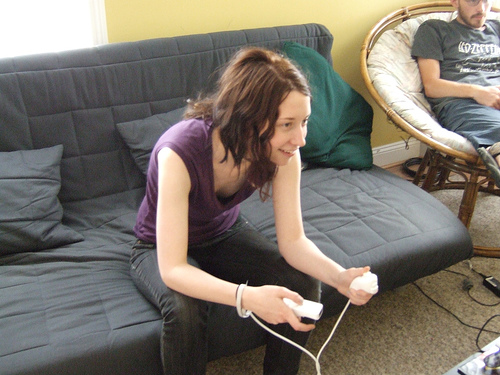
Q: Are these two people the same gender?
A: No, they are both male and female.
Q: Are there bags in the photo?
A: No, there are no bags.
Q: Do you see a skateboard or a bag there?
A: No, there are no bags or skateboards.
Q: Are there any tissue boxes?
A: No, there are no tissue boxes.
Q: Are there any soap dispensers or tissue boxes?
A: No, there are no tissue boxes or soap dispensers.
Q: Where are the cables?
A: The cables are on the floor.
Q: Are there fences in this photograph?
A: No, there are no fences.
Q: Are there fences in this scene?
A: No, there are no fences.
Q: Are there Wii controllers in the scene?
A: Yes, there is a Wii controller.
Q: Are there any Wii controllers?
A: Yes, there is a Wii controller.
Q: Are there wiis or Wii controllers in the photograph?
A: Yes, there is a Wii controller.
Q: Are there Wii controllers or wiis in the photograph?
A: Yes, there is a Wii controller.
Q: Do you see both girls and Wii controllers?
A: Yes, there are both a Wii controller and a girl.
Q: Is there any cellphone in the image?
A: No, there are no cell phones.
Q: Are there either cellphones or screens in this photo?
A: No, there are no cellphones or screens.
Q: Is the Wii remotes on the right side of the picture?
A: Yes, the Wii remotes is on the right of the image.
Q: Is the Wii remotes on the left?
A: No, the Wii remotes is on the right of the image.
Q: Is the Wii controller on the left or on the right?
A: The Wii controller is on the right of the image.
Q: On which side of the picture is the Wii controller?
A: The Wii controller is on the right of the image.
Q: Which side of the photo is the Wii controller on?
A: The Wii controller is on the right of the image.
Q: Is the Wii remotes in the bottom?
A: Yes, the Wii remotes is in the bottom of the image.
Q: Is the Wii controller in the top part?
A: No, the Wii controller is in the bottom of the image.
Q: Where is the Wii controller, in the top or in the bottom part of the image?
A: The Wii controller is in the bottom of the image.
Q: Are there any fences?
A: No, there are no fences.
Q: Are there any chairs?
A: Yes, there is a chair.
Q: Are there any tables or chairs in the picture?
A: Yes, there is a chair.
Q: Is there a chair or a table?
A: Yes, there is a chair.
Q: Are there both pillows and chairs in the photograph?
A: Yes, there are both a chair and a pillow.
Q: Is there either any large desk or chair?
A: Yes, there is a large chair.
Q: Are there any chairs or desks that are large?
A: Yes, the chair is large.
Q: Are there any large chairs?
A: Yes, there is a large chair.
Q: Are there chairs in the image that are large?
A: Yes, there is a chair that is large.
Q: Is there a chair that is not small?
A: Yes, there is a large chair.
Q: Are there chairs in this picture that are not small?
A: Yes, there is a large chair.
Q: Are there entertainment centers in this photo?
A: No, there are no entertainment centers.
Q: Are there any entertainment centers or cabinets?
A: No, there are no entertainment centers or cabinets.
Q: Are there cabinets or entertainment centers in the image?
A: No, there are no entertainment centers or cabinets.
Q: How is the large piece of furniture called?
A: The piece of furniture is a chair.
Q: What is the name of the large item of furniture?
A: The piece of furniture is a chair.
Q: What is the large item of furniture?
A: The piece of furniture is a chair.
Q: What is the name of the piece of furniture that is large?
A: The piece of furniture is a chair.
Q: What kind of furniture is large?
A: The furniture is a chair.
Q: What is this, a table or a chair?
A: This is a chair.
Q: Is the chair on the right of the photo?
A: Yes, the chair is on the right of the image.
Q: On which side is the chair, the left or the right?
A: The chair is on the right of the image.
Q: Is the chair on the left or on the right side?
A: The chair is on the right of the image.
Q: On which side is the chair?
A: The chair is on the right of the image.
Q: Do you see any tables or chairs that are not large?
A: No, there is a chair but it is large.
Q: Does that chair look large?
A: Yes, the chair is large.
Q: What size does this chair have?
A: The chair has large size.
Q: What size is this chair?
A: The chair is large.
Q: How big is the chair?
A: The chair is large.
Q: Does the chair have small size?
A: No, the chair is large.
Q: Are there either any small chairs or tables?
A: No, there is a chair but it is large.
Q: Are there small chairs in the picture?
A: No, there is a chair but it is large.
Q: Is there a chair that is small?
A: No, there is a chair but it is large.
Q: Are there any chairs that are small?
A: No, there is a chair but it is large.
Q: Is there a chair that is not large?
A: No, there is a chair but it is large.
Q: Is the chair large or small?
A: The chair is large.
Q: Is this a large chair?
A: Yes, this is a large chair.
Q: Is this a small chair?
A: No, this is a large chair.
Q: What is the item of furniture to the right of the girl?
A: The piece of furniture is a chair.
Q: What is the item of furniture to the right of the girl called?
A: The piece of furniture is a chair.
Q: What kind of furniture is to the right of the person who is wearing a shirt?
A: The piece of furniture is a chair.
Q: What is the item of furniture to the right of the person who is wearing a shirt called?
A: The piece of furniture is a chair.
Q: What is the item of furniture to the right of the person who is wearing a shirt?
A: The piece of furniture is a chair.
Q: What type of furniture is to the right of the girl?
A: The piece of furniture is a chair.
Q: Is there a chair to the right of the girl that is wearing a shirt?
A: Yes, there is a chair to the right of the girl.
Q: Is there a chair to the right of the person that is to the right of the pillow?
A: Yes, there is a chair to the right of the girl.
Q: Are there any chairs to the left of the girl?
A: No, the chair is to the right of the girl.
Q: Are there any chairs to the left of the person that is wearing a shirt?
A: No, the chair is to the right of the girl.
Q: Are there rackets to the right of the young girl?
A: No, there is a chair to the right of the girl.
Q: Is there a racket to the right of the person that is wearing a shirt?
A: No, there is a chair to the right of the girl.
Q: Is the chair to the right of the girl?
A: Yes, the chair is to the right of the girl.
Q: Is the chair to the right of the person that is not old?
A: Yes, the chair is to the right of the girl.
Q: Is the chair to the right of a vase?
A: No, the chair is to the right of the girl.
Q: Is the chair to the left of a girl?
A: No, the chair is to the right of a girl.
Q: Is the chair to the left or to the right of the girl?
A: The chair is to the right of the girl.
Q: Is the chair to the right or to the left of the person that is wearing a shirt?
A: The chair is to the right of the girl.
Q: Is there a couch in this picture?
A: Yes, there is a couch.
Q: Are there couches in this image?
A: Yes, there is a couch.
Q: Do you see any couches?
A: Yes, there is a couch.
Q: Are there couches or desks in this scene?
A: Yes, there is a couch.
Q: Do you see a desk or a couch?
A: Yes, there is a couch.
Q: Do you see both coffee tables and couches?
A: No, there is a couch but no coffee tables.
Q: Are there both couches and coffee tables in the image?
A: No, there is a couch but no coffee tables.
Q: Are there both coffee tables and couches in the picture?
A: No, there is a couch but no coffee tables.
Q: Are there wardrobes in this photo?
A: No, there are no wardrobes.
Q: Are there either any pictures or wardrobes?
A: No, there are no wardrobes or pictures.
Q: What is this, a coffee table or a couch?
A: This is a couch.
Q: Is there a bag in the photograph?
A: No, there are no bags.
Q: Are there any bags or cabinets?
A: No, there are no bags or cabinets.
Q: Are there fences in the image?
A: No, there are no fences.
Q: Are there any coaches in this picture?
A: No, there are no coaches.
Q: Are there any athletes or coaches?
A: No, there are no coaches or athletes.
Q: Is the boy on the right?
A: Yes, the boy is on the right of the image.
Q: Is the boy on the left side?
A: No, the boy is on the right of the image.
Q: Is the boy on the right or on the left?
A: The boy is on the right of the image.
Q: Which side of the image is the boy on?
A: The boy is on the right of the image.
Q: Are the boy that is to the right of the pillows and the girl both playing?
A: Yes, both the boy and the girl are playing.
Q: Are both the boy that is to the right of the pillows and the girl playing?
A: Yes, both the boy and the girl are playing.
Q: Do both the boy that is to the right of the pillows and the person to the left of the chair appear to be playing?
A: Yes, both the boy and the girl are playing.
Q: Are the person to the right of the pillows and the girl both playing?
A: Yes, both the boy and the girl are playing.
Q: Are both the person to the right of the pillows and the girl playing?
A: Yes, both the boy and the girl are playing.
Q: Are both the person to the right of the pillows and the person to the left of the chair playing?
A: Yes, both the boy and the girl are playing.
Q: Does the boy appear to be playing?
A: Yes, the boy is playing.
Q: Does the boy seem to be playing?
A: Yes, the boy is playing.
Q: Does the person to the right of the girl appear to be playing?
A: Yes, the boy is playing.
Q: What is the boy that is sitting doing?
A: The boy is playing.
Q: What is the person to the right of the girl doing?
A: The boy is playing.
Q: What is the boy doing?
A: The boy is playing.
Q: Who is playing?
A: The boy is playing.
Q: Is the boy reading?
A: No, the boy is playing.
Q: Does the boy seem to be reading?
A: No, the boy is playing.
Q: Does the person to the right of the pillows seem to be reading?
A: No, the boy is playing.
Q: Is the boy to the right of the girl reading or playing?
A: The boy is playing.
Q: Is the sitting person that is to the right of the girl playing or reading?
A: The boy is playing.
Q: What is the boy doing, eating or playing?
A: The boy is playing.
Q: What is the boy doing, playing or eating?
A: The boy is playing.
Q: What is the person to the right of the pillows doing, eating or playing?
A: The boy is playing.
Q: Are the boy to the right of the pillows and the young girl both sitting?
A: Yes, both the boy and the girl are sitting.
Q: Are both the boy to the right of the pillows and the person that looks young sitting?
A: Yes, both the boy and the girl are sitting.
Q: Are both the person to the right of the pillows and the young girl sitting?
A: Yes, both the boy and the girl are sitting.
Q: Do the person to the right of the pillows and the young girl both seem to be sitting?
A: Yes, both the boy and the girl are sitting.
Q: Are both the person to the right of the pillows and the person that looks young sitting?
A: Yes, both the boy and the girl are sitting.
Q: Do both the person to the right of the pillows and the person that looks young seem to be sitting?
A: Yes, both the boy and the girl are sitting.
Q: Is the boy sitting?
A: Yes, the boy is sitting.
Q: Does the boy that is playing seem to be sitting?
A: Yes, the boy is sitting.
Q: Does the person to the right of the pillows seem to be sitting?
A: Yes, the boy is sitting.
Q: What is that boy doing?
A: The boy is sitting.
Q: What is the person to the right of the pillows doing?
A: The boy is sitting.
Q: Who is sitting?
A: The boy is sitting.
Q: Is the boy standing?
A: No, the boy is sitting.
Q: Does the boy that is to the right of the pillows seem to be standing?
A: No, the boy is sitting.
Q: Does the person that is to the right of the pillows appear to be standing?
A: No, the boy is sitting.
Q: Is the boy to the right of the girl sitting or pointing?
A: The boy is sitting.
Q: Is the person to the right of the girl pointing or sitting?
A: The boy is sitting.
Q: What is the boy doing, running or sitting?
A: The boy is sitting.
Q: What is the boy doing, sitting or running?
A: The boy is sitting.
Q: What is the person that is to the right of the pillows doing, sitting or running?
A: The boy is sitting.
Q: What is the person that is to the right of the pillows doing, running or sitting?
A: The boy is sitting.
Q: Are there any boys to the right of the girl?
A: Yes, there is a boy to the right of the girl.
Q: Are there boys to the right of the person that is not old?
A: Yes, there is a boy to the right of the girl.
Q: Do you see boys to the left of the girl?
A: No, the boy is to the right of the girl.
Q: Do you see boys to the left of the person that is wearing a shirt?
A: No, the boy is to the right of the girl.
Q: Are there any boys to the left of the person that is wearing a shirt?
A: No, the boy is to the right of the girl.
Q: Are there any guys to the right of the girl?
A: No, there is a boy to the right of the girl.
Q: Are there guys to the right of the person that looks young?
A: No, there is a boy to the right of the girl.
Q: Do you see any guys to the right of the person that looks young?
A: No, there is a boy to the right of the girl.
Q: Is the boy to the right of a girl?
A: Yes, the boy is to the right of a girl.